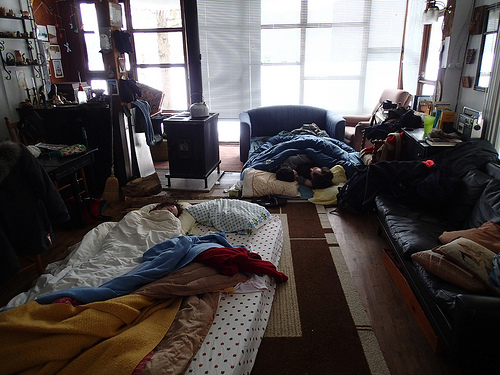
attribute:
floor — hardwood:
[0, 143, 498, 374]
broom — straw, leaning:
[100, 84, 122, 203]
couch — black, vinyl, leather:
[375, 172, 499, 360]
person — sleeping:
[273, 153, 311, 183]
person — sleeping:
[305, 149, 353, 196]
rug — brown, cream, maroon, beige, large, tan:
[178, 198, 387, 374]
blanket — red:
[195, 248, 289, 285]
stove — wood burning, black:
[162, 111, 222, 191]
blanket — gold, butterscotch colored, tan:
[0, 293, 182, 374]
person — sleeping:
[149, 201, 183, 219]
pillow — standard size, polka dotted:
[186, 198, 273, 233]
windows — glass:
[261, 1, 427, 118]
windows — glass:
[77, 3, 190, 112]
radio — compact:
[455, 106, 484, 140]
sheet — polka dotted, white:
[186, 215, 284, 375]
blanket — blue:
[34, 233, 247, 306]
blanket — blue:
[236, 131, 361, 182]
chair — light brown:
[343, 89, 415, 151]